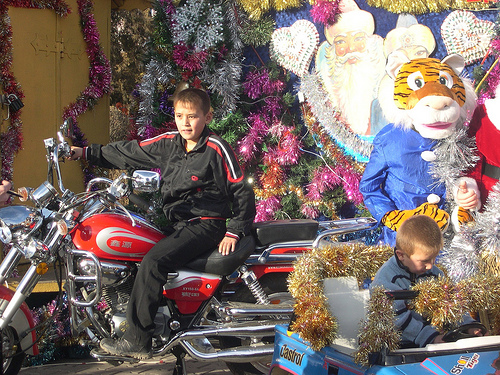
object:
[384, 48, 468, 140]
head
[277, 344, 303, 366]
black lettering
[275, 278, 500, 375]
ride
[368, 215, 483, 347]
boy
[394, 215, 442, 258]
hair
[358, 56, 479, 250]
mascot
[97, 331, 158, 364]
sneakers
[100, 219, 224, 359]
pants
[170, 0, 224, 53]
snowflake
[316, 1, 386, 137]
santa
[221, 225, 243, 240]
cuff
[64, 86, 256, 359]
boy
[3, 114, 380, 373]
motorcycle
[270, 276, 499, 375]
car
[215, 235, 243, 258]
left hand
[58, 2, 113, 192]
pink tinsel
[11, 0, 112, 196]
wall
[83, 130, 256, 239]
jacket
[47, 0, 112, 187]
tinsel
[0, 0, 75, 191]
tinsel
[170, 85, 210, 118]
hair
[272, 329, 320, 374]
blue